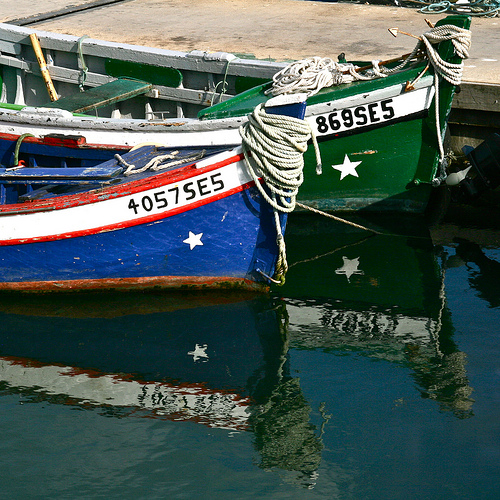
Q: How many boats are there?
A: Two.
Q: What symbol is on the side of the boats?
A: Star.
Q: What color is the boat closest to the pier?
A: Green.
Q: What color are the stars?
A: White.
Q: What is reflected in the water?
A: Boats.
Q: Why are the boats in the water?
A: Docking.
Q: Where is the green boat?
A: Near dock.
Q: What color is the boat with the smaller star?
A: Red. white, and blue.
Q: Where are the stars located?
A: Nose of boat.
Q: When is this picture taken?
A: Morning.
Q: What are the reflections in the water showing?
A: The boat.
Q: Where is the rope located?
A: Nose of boat.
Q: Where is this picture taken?
A: Water.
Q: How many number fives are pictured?
A: Three.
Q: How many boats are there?
A: 2.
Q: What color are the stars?
A: White.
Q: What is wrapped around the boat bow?
A: Rope.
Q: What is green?
A: Boat closest to dock.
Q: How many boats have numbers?
A: 2.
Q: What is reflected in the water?
A: 2 boats.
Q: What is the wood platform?
A: Dock.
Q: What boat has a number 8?
A: Green boat.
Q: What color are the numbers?
A: Black.